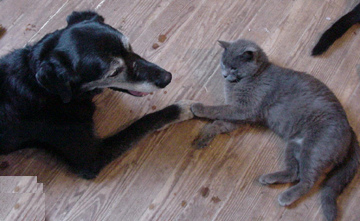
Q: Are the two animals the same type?
A: No, they are dogs and cats.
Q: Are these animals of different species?
A: Yes, they are dogs and cats.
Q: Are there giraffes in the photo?
A: No, there are no giraffes.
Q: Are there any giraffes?
A: No, there are no giraffes.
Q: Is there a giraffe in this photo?
A: No, there are no giraffes.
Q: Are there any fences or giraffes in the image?
A: No, there are no giraffes or fences.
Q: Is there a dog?
A: Yes, there is a dog.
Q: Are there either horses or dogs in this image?
A: Yes, there is a dog.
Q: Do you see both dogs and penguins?
A: No, there is a dog but no penguins.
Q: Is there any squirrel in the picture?
A: No, there are no squirrels.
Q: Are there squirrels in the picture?
A: No, there are no squirrels.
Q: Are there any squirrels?
A: No, there are no squirrels.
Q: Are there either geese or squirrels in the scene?
A: No, there are no squirrels or geese.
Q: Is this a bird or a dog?
A: This is a dog.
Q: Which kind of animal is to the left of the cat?
A: The animal is a dog.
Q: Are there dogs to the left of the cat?
A: Yes, there is a dog to the left of the cat.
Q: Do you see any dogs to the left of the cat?
A: Yes, there is a dog to the left of the cat.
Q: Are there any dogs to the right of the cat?
A: No, the dog is to the left of the cat.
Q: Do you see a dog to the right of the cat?
A: No, the dog is to the left of the cat.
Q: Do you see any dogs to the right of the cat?
A: No, the dog is to the left of the cat.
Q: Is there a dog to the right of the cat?
A: No, the dog is to the left of the cat.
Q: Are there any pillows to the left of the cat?
A: No, there is a dog to the left of the cat.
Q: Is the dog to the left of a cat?
A: Yes, the dog is to the left of a cat.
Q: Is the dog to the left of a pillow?
A: No, the dog is to the left of a cat.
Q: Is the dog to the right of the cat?
A: No, the dog is to the left of the cat.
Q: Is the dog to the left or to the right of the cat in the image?
A: The dog is to the left of the cat.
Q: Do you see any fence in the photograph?
A: No, there are no fences.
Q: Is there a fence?
A: No, there are no fences.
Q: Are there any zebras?
A: No, there are no zebras.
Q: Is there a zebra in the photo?
A: No, there are no zebras.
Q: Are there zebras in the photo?
A: No, there are no zebras.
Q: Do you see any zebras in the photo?
A: No, there are no zebras.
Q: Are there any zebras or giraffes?
A: No, there are no zebras or giraffes.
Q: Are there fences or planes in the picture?
A: No, there are no fences or planes.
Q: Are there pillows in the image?
A: No, there are no pillows.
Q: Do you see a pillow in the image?
A: No, there are no pillows.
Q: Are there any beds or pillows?
A: No, there are no pillows or beds.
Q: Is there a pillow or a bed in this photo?
A: No, there are no pillows or beds.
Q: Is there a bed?
A: No, there are no beds.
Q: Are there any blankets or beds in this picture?
A: No, there are no beds or blankets.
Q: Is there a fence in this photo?
A: No, there are no fences.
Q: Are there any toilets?
A: No, there are no toilets.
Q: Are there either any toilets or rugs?
A: No, there are no toilets or rugs.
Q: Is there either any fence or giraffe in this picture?
A: No, there are no giraffes or fences.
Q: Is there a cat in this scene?
A: Yes, there is a cat.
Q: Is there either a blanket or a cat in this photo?
A: Yes, there is a cat.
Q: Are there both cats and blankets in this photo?
A: No, there is a cat but no blankets.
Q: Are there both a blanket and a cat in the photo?
A: No, there is a cat but no blankets.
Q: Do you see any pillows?
A: No, there are no pillows.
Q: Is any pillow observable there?
A: No, there are no pillows.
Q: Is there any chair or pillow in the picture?
A: No, there are no pillows or chairs.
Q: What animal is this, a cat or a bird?
A: This is a cat.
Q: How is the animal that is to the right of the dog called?
A: The animal is a cat.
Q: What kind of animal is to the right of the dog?
A: The animal is a cat.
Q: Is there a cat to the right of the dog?
A: Yes, there is a cat to the right of the dog.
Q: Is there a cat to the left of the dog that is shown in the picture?
A: No, the cat is to the right of the dog.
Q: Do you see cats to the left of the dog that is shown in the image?
A: No, the cat is to the right of the dog.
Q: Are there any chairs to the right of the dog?
A: No, there is a cat to the right of the dog.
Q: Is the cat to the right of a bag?
A: No, the cat is to the right of the dog.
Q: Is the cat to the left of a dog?
A: No, the cat is to the right of a dog.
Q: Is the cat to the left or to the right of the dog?
A: The cat is to the right of the dog.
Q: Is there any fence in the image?
A: No, there are no fences.